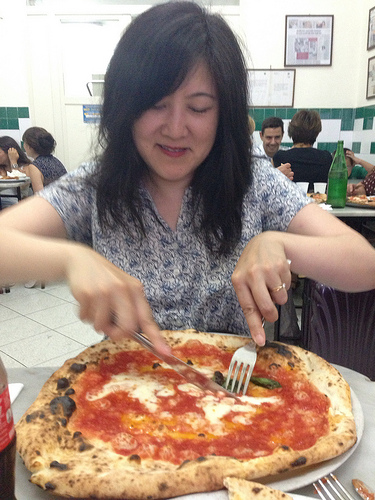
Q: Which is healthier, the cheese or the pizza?
A: The cheese is healthier than the pizza.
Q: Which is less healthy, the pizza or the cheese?
A: The pizza is less healthy than the cheese.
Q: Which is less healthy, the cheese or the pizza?
A: The pizza is less healthy than the cheese.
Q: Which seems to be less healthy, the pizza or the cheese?
A: The pizza is less healthy than the cheese.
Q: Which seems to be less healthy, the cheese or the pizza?
A: The pizza is less healthy than the cheese.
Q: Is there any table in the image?
A: Yes, there is a table.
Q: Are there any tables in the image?
A: Yes, there is a table.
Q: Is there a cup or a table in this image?
A: Yes, there is a table.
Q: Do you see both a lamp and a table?
A: No, there is a table but no lamps.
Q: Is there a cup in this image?
A: No, there are no cups.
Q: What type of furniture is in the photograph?
A: The furniture is a table.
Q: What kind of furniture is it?
A: The piece of furniture is a table.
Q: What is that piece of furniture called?
A: This is a table.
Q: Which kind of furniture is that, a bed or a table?
A: This is a table.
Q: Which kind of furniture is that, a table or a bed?
A: This is a table.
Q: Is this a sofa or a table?
A: This is a table.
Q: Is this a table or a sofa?
A: This is a table.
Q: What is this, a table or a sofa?
A: This is a table.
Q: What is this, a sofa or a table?
A: This is a table.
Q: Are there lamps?
A: No, there are no lamps.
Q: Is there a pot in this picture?
A: No, there are no pots.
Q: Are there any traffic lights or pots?
A: No, there are no pots or traffic lights.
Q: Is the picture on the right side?
A: Yes, the picture is on the right of the image.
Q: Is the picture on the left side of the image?
A: No, the picture is on the right of the image.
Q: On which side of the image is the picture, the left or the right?
A: The picture is on the right of the image.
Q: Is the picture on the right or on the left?
A: The picture is on the right of the image.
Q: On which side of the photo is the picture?
A: The picture is on the right of the image.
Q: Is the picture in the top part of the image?
A: Yes, the picture is in the top of the image.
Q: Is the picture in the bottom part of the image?
A: No, the picture is in the top of the image.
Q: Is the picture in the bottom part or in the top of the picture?
A: The picture is in the top of the image.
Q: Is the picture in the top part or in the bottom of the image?
A: The picture is in the top of the image.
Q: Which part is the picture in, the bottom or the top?
A: The picture is in the top of the image.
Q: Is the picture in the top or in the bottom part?
A: The picture is in the top of the image.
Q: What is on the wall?
A: The picture is on the wall.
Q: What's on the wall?
A: The picture is on the wall.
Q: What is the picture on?
A: The picture is on the wall.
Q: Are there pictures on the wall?
A: Yes, there is a picture on the wall.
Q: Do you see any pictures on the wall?
A: Yes, there is a picture on the wall.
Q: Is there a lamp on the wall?
A: No, there is a picture on the wall.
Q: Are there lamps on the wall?
A: No, there is a picture on the wall.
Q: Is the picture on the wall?
A: Yes, the picture is on the wall.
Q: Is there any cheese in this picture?
A: Yes, there is cheese.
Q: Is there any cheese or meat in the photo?
A: Yes, there is cheese.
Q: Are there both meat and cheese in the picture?
A: No, there is cheese but no meat.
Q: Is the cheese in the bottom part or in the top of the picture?
A: The cheese is in the bottom of the image.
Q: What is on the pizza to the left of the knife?
A: The cheese is on the pizza.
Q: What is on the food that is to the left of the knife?
A: The cheese is on the pizza.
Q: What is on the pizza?
A: The cheese is on the pizza.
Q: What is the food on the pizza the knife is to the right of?
A: The food is cheese.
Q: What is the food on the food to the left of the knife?
A: The food is cheese.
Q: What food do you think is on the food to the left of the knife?
A: The food is cheese.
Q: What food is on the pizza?
A: The food is cheese.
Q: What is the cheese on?
A: The cheese is on the pizza.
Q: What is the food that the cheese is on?
A: The food is a pizza.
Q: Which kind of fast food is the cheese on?
A: The cheese is on the pizza.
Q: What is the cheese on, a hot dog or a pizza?
A: The cheese is on a pizza.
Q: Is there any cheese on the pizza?
A: Yes, there is cheese on the pizza.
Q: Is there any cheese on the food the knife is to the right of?
A: Yes, there is cheese on the pizza.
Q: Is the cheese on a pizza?
A: Yes, the cheese is on a pizza.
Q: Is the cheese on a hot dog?
A: No, the cheese is on a pizza.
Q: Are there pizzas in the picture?
A: Yes, there is a pizza.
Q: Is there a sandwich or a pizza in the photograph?
A: Yes, there is a pizza.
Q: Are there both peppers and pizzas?
A: No, there is a pizza but no peppers.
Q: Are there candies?
A: No, there are no candies.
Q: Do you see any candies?
A: No, there are no candies.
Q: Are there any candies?
A: No, there are no candies.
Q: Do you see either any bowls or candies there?
A: No, there are no candies or bowls.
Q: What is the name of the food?
A: The food is a pizza.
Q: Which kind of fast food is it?
A: The food is a pizza.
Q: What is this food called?
A: This is a pizza.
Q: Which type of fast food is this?
A: This is a pizza.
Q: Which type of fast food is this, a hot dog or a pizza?
A: This is a pizza.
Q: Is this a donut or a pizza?
A: This is a pizza.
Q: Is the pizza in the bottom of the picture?
A: Yes, the pizza is in the bottom of the image.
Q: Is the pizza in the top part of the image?
A: No, the pizza is in the bottom of the image.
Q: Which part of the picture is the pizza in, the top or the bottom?
A: The pizza is in the bottom of the image.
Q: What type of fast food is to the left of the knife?
A: The food is a pizza.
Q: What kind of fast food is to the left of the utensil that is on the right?
A: The food is a pizza.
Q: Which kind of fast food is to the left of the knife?
A: The food is a pizza.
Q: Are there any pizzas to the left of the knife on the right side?
A: Yes, there is a pizza to the left of the knife.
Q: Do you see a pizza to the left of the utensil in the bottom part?
A: Yes, there is a pizza to the left of the knife.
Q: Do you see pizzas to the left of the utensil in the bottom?
A: Yes, there is a pizza to the left of the knife.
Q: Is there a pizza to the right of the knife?
A: No, the pizza is to the left of the knife.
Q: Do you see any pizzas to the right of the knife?
A: No, the pizza is to the left of the knife.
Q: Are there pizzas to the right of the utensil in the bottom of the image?
A: No, the pizza is to the left of the knife.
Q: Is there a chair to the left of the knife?
A: No, there is a pizza to the left of the knife.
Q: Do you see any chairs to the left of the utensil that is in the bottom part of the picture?
A: No, there is a pizza to the left of the knife.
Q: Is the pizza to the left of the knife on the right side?
A: Yes, the pizza is to the left of the knife.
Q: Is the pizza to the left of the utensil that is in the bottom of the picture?
A: Yes, the pizza is to the left of the knife.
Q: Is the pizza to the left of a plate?
A: No, the pizza is to the left of the knife.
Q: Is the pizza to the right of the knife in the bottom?
A: No, the pizza is to the left of the knife.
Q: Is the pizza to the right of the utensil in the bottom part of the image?
A: No, the pizza is to the left of the knife.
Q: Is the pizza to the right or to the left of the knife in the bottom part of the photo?
A: The pizza is to the left of the knife.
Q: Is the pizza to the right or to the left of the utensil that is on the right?
A: The pizza is to the left of the knife.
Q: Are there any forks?
A: Yes, there is a fork.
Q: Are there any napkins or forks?
A: Yes, there is a fork.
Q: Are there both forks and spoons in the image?
A: No, there is a fork but no spoons.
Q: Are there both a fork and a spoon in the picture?
A: No, there is a fork but no spoons.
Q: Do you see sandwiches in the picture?
A: No, there are no sandwiches.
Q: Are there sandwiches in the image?
A: No, there are no sandwiches.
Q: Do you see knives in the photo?
A: Yes, there is a knife.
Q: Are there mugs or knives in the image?
A: Yes, there is a knife.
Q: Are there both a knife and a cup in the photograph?
A: No, there is a knife but no cups.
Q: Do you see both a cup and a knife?
A: No, there is a knife but no cups.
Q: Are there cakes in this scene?
A: No, there are no cakes.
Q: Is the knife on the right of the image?
A: Yes, the knife is on the right of the image.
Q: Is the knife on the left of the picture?
A: No, the knife is on the right of the image.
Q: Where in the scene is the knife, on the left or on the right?
A: The knife is on the right of the image.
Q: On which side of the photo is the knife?
A: The knife is on the right of the image.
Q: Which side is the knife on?
A: The knife is on the right of the image.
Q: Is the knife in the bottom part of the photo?
A: Yes, the knife is in the bottom of the image.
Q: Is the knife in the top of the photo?
A: No, the knife is in the bottom of the image.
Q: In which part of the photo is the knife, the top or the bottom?
A: The knife is in the bottom of the image.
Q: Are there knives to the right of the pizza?
A: Yes, there is a knife to the right of the pizza.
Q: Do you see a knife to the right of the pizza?
A: Yes, there is a knife to the right of the pizza.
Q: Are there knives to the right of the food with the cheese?
A: Yes, there is a knife to the right of the pizza.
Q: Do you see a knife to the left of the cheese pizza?
A: No, the knife is to the right of the pizza.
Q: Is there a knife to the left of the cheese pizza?
A: No, the knife is to the right of the pizza.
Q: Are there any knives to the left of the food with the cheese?
A: No, the knife is to the right of the pizza.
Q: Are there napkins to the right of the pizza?
A: No, there is a knife to the right of the pizza.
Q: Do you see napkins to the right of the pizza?
A: No, there is a knife to the right of the pizza.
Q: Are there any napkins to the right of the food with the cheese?
A: No, there is a knife to the right of the pizza.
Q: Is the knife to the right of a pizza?
A: Yes, the knife is to the right of a pizza.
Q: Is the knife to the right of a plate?
A: No, the knife is to the right of a pizza.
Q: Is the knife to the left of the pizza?
A: No, the knife is to the right of the pizza.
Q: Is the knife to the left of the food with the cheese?
A: No, the knife is to the right of the pizza.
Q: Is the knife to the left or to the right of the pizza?
A: The knife is to the right of the pizza.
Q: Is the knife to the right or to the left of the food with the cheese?
A: The knife is to the right of the pizza.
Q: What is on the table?
A: The glass is on the table.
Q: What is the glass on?
A: The glass is on the table.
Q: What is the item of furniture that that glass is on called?
A: The piece of furniture is a table.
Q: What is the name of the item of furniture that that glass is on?
A: The piece of furniture is a table.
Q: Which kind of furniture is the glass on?
A: The glass is on the table.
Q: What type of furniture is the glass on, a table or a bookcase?
A: The glass is on a table.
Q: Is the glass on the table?
A: Yes, the glass is on the table.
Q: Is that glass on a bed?
A: No, the glass is on the table.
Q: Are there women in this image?
A: Yes, there is a woman.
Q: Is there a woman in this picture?
A: Yes, there is a woman.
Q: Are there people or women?
A: Yes, there is a woman.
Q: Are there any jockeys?
A: No, there are no jockeys.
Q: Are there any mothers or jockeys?
A: No, there are no jockeys or mothers.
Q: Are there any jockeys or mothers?
A: No, there are no jockeys or mothers.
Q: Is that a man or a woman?
A: That is a woman.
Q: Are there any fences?
A: No, there are no fences.